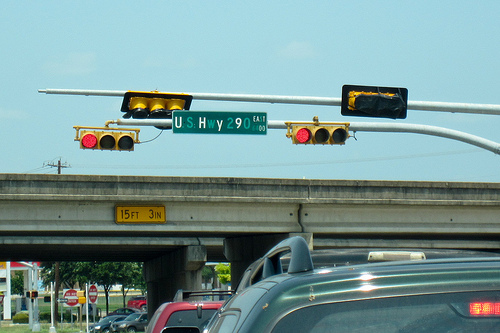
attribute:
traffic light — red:
[79, 130, 138, 152]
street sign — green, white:
[172, 112, 267, 133]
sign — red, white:
[64, 288, 95, 303]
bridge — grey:
[0, 173, 500, 238]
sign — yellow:
[113, 205, 167, 221]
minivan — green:
[224, 265, 500, 330]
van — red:
[148, 300, 214, 331]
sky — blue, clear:
[1, 4, 499, 179]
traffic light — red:
[291, 124, 349, 143]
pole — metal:
[117, 117, 498, 150]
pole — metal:
[40, 84, 496, 116]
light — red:
[81, 132, 99, 150]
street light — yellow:
[122, 95, 187, 112]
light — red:
[297, 129, 313, 143]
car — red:
[126, 296, 150, 310]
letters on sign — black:
[147, 207, 165, 221]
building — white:
[1, 264, 54, 302]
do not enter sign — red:
[64, 288, 83, 306]